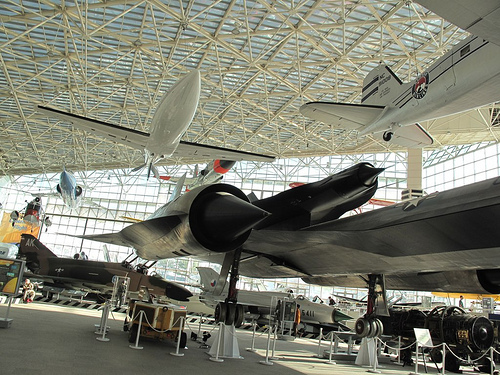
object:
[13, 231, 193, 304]
plane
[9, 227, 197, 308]
aircraft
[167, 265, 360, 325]
aircraft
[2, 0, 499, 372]
aircraft exhibit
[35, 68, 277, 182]
plane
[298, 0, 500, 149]
plane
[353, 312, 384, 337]
wheels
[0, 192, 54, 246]
helicopter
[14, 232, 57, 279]
tail section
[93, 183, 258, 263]
jet engine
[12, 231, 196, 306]
jet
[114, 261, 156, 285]
cockpit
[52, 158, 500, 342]
aircraft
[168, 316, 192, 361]
stanchions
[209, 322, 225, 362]
stanchions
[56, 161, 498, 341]
exhibits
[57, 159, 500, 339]
jet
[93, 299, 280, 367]
barriers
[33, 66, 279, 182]
jet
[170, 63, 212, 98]
nose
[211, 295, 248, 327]
gears